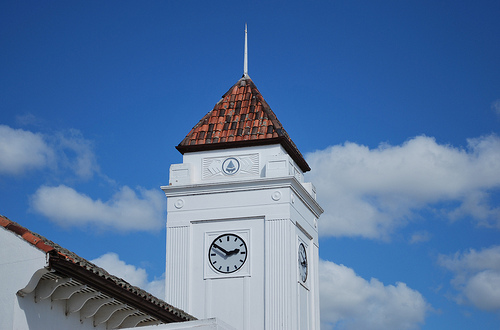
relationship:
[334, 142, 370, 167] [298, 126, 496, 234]
part of cloud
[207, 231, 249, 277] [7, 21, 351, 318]
clock on building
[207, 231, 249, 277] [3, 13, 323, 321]
clock on building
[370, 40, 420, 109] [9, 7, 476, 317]
part of sky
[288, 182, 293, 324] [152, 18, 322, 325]
edge of a tower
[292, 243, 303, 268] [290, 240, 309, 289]
part of a clock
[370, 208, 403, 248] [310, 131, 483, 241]
edge of a cloud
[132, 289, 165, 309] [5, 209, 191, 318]
edge of a roof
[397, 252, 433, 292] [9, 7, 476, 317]
part of sky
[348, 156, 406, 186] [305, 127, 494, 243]
part of cloud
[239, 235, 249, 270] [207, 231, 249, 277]
edge of clock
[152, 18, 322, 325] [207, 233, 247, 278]
tower has clock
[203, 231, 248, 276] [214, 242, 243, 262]
clock has hands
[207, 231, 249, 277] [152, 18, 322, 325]
clock on tower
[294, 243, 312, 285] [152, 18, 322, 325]
clock on tower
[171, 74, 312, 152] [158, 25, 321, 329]
roof of tower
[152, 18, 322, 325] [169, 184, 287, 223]
tower has trim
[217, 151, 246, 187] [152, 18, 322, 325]
logo on tower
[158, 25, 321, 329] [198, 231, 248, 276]
tower has clock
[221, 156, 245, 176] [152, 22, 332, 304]
design on tower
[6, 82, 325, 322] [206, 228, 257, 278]
building with clock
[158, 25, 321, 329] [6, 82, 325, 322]
tower attached to building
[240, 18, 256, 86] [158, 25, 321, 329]
top of tower